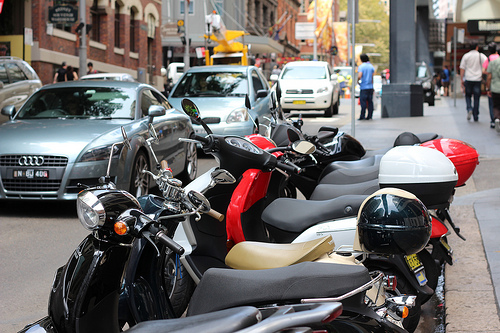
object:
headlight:
[74, 192, 107, 232]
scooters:
[14, 300, 344, 332]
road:
[1, 96, 500, 332]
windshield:
[16, 86, 138, 120]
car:
[1, 79, 196, 202]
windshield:
[173, 70, 248, 97]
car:
[169, 65, 280, 155]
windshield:
[279, 65, 325, 80]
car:
[267, 59, 344, 117]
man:
[355, 51, 377, 122]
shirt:
[357, 62, 376, 93]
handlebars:
[142, 227, 184, 257]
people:
[456, 44, 488, 122]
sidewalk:
[353, 90, 500, 333]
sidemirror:
[145, 104, 167, 119]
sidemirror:
[180, 96, 200, 120]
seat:
[223, 234, 337, 269]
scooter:
[48, 176, 420, 332]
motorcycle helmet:
[353, 186, 439, 260]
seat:
[186, 263, 371, 316]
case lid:
[376, 144, 461, 184]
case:
[420, 136, 481, 185]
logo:
[19, 155, 47, 167]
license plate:
[11, 168, 51, 183]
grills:
[3, 180, 60, 193]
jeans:
[359, 88, 375, 119]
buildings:
[0, 1, 351, 92]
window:
[138, 91, 160, 117]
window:
[249, 70, 266, 101]